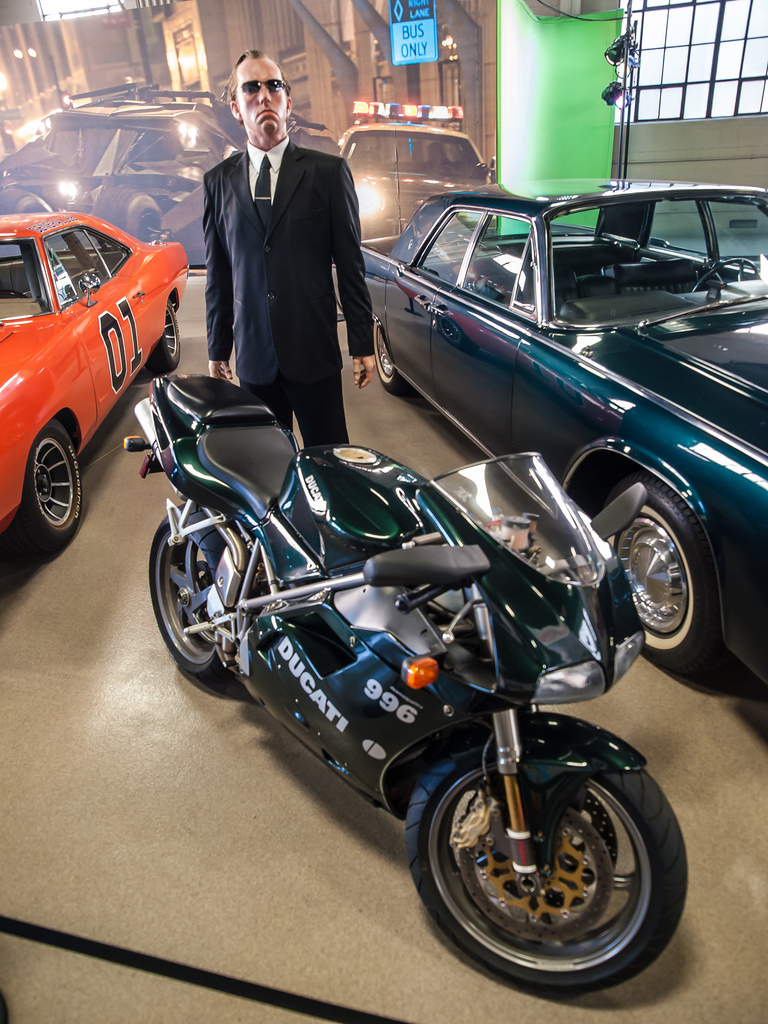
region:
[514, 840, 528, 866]
A red small stripe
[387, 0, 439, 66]
A blue signage hanging.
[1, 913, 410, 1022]
A black stripe on floor.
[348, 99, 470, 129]
Police lights on top of car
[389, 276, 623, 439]
A reflection of red car.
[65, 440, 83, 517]
White letterings on the side of wheel.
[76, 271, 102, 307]
A small and shiny side mirror.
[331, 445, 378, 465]
A round with gold in the center.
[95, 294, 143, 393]
Black with white border numbers.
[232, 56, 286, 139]
A man's face with sunglasses.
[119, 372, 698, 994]
a black motorcycle sitting in the garage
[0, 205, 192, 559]
an orange and black car designed like the "General Lee"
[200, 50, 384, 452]
a man wearing a black suit and sunglasses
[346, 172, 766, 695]
a black car sitting in the garage next to the man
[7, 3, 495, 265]
a mural showing a car being chased by a cop car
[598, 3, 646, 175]
the pole holding onto two large lights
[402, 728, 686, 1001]
the front wheel of the bike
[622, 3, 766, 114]
the windows high on the wall of the garage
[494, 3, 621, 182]
the green screen next to the lights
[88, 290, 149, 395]
the number written on the side of the car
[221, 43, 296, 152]
A man wearing sunglasses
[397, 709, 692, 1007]
The front tire of a motorcycle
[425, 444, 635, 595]
the fairing on a motorcycle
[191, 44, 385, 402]
A man wearing a black suit and tie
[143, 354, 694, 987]
a shiny black motorcycle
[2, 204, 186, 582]
an orange vehicle from a TV show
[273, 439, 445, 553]
The gas tank on a motorcycle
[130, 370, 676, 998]
a Ducati motorcycle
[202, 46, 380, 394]
a man wearing a black suit jacket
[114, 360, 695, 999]
black motorcycle with Ducati logo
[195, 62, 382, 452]
man wearing dark suit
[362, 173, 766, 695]
black American sedan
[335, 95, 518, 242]
police car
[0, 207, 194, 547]
red car with numbers 01 on door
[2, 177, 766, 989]
motorcycle is parked between two cars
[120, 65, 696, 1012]
man stands behind motorcyle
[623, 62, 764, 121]
window with multiple panes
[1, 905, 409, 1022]
off-white floor has a black stripe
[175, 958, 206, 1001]
Long black strip of paint on the ground.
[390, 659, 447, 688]
Orange reflector light on the side of the bike.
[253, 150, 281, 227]
Black tie on the man's body.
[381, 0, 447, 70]
Bus only sign on the top of the pole.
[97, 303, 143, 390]
Black and white numbers on the side of the car.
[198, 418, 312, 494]
Black seat on the motorcycle.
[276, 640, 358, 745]
Brand of the motorcycle painted on.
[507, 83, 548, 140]
Green screen by the windows.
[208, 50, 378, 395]
the man is dressed in a black suit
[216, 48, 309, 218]
the man is wearing a white shirt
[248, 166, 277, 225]
The man is wearing a black tie.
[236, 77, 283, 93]
The man is wearing black shades.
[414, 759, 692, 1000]
The tire is round.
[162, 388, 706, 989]
A motorcycle parked in front of the man.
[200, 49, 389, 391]
The man is wearing a black suit.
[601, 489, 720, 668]
The tire has white walls.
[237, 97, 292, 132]
The man is frowning.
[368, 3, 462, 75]
a sign above the car.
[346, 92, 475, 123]
Sirens on top of the car.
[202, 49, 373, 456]
a person dressed for an MIB movie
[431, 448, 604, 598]
low slung windshield of the motorcycle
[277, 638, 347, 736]
a brand of the motorcycle